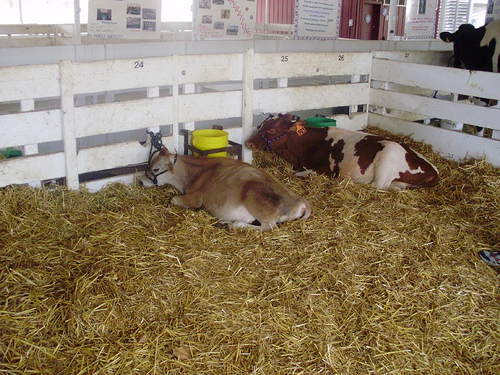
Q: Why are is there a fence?
A: To hold the cattle.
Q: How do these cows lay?
A: On their stomachs.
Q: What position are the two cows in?
A: Laying down.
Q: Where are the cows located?
A: Cow pen.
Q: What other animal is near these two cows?
A: Another cow.